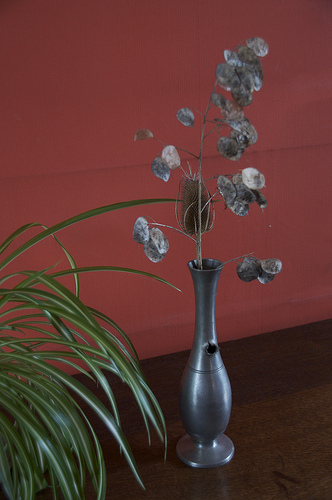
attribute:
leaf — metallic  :
[260, 257, 282, 273]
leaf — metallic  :
[161, 144, 182, 168]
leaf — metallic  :
[144, 226, 167, 262]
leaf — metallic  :
[176, 106, 194, 125]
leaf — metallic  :
[246, 36, 270, 57]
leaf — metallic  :
[230, 69, 252, 107]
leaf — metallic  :
[214, 63, 243, 90]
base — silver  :
[176, 256, 236, 466]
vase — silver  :
[177, 257, 234, 470]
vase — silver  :
[175, 257, 237, 465]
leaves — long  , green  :
[2, 195, 183, 356]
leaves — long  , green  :
[1, 296, 148, 388]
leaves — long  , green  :
[1, 383, 164, 465]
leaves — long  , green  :
[1, 430, 150, 497]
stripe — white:
[77, 390, 108, 423]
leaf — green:
[18, 350, 150, 492]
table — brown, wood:
[87, 323, 330, 496]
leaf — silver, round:
[132, 216, 150, 244]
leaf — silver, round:
[241, 163, 264, 191]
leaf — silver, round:
[235, 254, 255, 281]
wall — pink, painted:
[0, 3, 330, 373]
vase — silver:
[169, 255, 236, 467]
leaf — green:
[10, 189, 179, 275]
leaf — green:
[11, 268, 93, 318]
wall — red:
[1, 92, 327, 385]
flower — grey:
[131, 217, 152, 245]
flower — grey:
[149, 155, 173, 179]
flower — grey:
[175, 103, 197, 128]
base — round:
[178, 432, 236, 466]